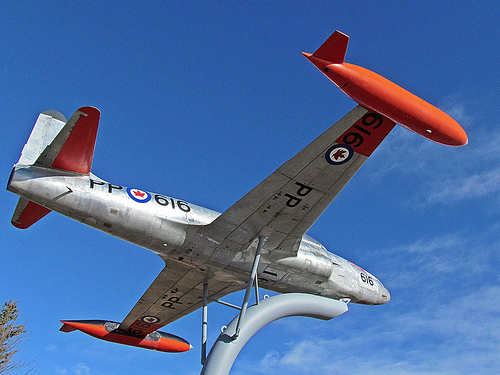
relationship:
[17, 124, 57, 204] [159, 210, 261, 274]
tail of plane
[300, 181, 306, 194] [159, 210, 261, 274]
letter on plane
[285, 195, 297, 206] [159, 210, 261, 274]
letter on plane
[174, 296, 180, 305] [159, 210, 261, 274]
letter on plane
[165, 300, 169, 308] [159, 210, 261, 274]
letter on plane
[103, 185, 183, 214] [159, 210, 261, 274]
writing on plane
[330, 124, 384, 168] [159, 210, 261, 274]
writing on plane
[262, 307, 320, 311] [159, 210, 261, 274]
beam under plane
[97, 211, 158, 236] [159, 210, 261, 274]
belly of plane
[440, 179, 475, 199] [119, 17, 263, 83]
cloud in sky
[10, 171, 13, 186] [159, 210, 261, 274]
exhaust of plane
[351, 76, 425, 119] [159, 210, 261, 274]
side engine of plane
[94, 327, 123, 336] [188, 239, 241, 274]
side engine of plan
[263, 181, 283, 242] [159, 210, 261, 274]
wing of plane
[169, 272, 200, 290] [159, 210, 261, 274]
wing of plane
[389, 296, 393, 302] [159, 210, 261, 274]
tip of plane